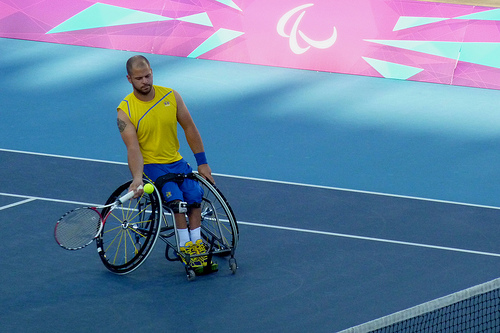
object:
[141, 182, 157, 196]
ball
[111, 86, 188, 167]
shirt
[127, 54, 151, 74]
hair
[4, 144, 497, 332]
tennis court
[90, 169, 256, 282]
wheelchair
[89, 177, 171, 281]
wheel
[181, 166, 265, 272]
wheel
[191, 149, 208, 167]
wristband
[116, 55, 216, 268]
man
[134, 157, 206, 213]
blue shorts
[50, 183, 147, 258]
racket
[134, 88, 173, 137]
stripe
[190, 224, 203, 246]
sock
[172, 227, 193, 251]
sock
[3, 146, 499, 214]
line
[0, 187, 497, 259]
line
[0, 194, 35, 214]
line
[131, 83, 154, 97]
beard